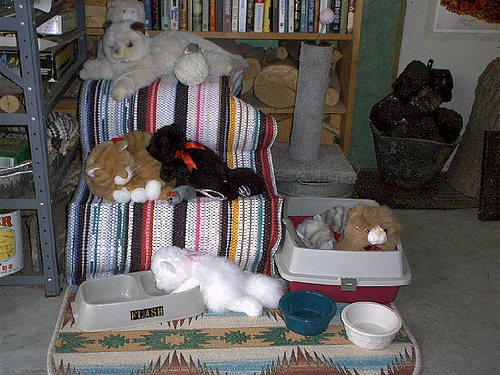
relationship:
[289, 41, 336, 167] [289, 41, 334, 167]
carpet on carpet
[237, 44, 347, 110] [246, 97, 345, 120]
firewood on shelf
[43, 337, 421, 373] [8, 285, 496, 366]
towel on floor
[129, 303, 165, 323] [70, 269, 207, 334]
woods are on dish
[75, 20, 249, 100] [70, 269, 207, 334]
animal laying in dish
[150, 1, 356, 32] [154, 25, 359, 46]
books are on shelf